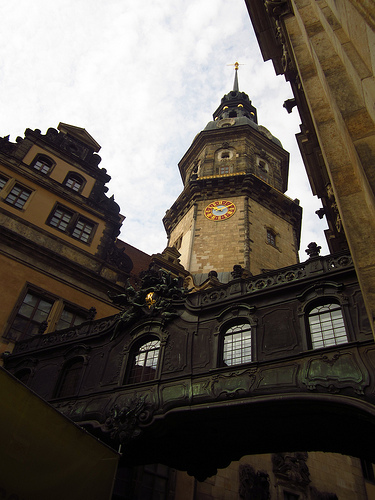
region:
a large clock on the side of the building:
[204, 198, 234, 218]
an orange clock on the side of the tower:
[204, 199, 236, 218]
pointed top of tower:
[231, 59, 239, 91]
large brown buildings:
[0, 1, 373, 496]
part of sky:
[0, 2, 325, 266]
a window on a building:
[220, 316, 258, 371]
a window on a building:
[135, 333, 151, 365]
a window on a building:
[74, 217, 94, 239]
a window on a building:
[37, 155, 50, 170]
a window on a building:
[63, 172, 75, 190]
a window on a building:
[7, 183, 32, 211]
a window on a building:
[59, 305, 89, 327]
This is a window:
[210, 312, 270, 387]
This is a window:
[24, 148, 55, 179]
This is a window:
[127, 326, 165, 383]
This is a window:
[56, 295, 86, 343]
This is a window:
[8, 264, 50, 333]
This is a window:
[216, 139, 231, 162]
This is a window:
[255, 214, 285, 264]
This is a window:
[64, 162, 87, 201]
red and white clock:
[203, 194, 237, 225]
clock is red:
[205, 202, 234, 218]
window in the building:
[212, 316, 252, 364]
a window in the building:
[295, 299, 356, 348]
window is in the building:
[124, 334, 164, 384]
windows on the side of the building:
[50, 197, 96, 246]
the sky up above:
[49, 13, 197, 109]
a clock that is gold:
[201, 202, 244, 219]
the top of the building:
[217, 59, 253, 90]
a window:
[260, 227, 280, 245]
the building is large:
[1, 0, 374, 499]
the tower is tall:
[162, 63, 304, 289]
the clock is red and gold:
[204, 199, 236, 220]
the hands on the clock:
[204, 199, 237, 219]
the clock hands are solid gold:
[204, 198, 237, 219]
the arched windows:
[215, 315, 253, 366]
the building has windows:
[1, 1, 374, 499]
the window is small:
[264, 226, 278, 246]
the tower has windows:
[162, 60, 304, 291]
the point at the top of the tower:
[163, 61, 304, 266]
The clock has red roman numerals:
[199, 199, 240, 227]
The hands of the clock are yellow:
[210, 202, 229, 212]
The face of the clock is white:
[203, 202, 235, 219]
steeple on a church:
[226, 57, 246, 92]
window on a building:
[125, 335, 161, 380]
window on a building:
[216, 317, 253, 363]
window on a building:
[304, 301, 350, 347]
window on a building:
[5, 278, 52, 338]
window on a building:
[55, 301, 87, 331]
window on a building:
[47, 203, 68, 235]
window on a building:
[71, 213, 96, 245]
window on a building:
[33, 154, 50, 174]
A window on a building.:
[209, 308, 251, 366]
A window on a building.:
[294, 290, 353, 352]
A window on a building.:
[121, 330, 173, 378]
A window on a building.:
[53, 358, 96, 403]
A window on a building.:
[69, 208, 97, 248]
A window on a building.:
[44, 199, 75, 232]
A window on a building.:
[32, 151, 56, 180]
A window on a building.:
[6, 177, 31, 217]